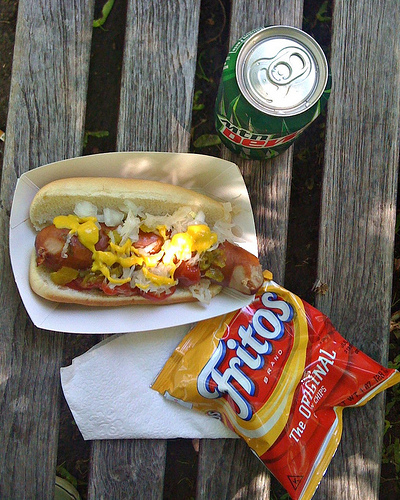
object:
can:
[212, 25, 329, 162]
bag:
[151, 268, 399, 499]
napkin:
[59, 321, 242, 440]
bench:
[0, 2, 399, 500]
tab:
[268, 47, 312, 85]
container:
[9, 151, 260, 334]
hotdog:
[34, 224, 265, 295]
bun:
[29, 176, 234, 228]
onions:
[74, 200, 99, 219]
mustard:
[52, 214, 216, 286]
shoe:
[55, 476, 82, 499]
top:
[236, 24, 329, 119]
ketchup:
[173, 259, 201, 288]